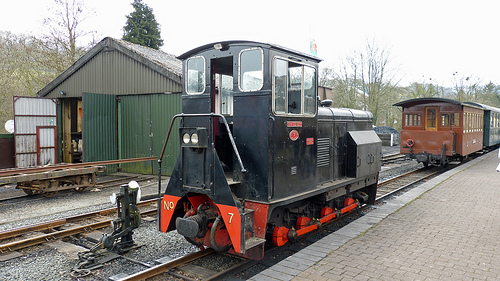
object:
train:
[155, 42, 384, 255]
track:
[2, 154, 447, 279]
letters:
[162, 196, 175, 213]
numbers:
[225, 210, 235, 222]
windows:
[185, 56, 216, 96]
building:
[8, 40, 189, 182]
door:
[14, 94, 57, 165]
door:
[82, 91, 117, 172]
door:
[119, 94, 153, 174]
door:
[151, 93, 183, 175]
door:
[206, 56, 237, 184]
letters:
[286, 116, 304, 142]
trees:
[339, 46, 394, 140]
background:
[2, 0, 500, 281]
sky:
[1, 1, 498, 91]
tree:
[123, 0, 164, 50]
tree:
[48, 0, 97, 74]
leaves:
[12, 50, 30, 68]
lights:
[179, 131, 194, 143]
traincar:
[391, 95, 499, 171]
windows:
[424, 105, 439, 132]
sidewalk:
[251, 146, 497, 281]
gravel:
[2, 145, 409, 279]